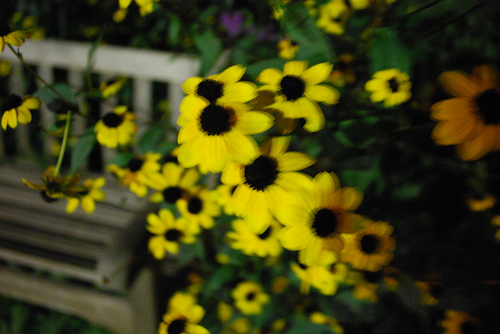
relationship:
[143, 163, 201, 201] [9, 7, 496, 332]
flower is on plant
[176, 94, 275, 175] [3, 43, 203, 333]
flower is by seating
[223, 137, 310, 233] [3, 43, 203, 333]
flowers is by seating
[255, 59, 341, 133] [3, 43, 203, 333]
flower is by seating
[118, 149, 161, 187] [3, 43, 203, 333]
flower is by seating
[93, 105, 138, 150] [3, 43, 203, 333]
flower is by seating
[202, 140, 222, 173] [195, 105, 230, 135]
petal is around center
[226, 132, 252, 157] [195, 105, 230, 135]
petal is around center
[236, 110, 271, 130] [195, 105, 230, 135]
petal is around center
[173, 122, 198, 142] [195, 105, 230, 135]
petal is around center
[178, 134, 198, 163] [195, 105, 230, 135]
petal is around center